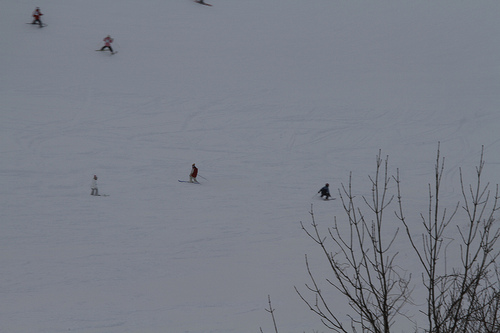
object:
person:
[29, 5, 44, 30]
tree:
[257, 141, 499, 333]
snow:
[0, 2, 498, 331]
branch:
[391, 167, 426, 274]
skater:
[87, 173, 101, 197]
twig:
[297, 219, 320, 247]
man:
[186, 162, 201, 184]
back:
[194, 165, 197, 179]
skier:
[314, 182, 330, 203]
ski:
[174, 179, 204, 183]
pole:
[310, 192, 320, 200]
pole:
[196, 172, 213, 183]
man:
[190, 0, 218, 8]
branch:
[263, 294, 280, 333]